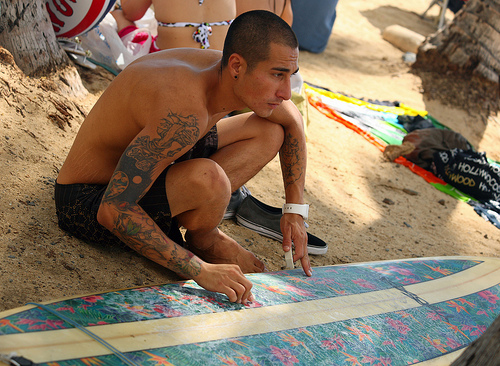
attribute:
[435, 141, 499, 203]
object — black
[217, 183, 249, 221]
sneakers — black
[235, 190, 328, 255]
sneakers — black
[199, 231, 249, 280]
foot — bare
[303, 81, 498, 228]
towel — beach towel